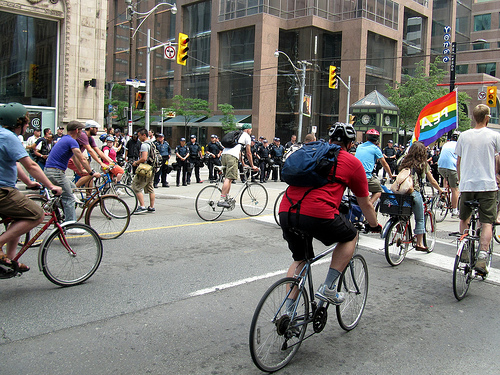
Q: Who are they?
A: Cyclists.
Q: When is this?
A: Daytime.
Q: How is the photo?
A: Clear.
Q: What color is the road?
A: Gray.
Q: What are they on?
A: Bicycles.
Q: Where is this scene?
A: On street.